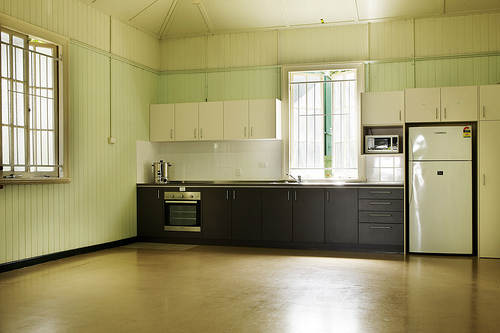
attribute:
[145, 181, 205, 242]
oven — silver oven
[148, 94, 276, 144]
cabinets — dark 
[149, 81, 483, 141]
cabinets — white 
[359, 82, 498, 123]
cabinets — white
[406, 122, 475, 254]
fridge — white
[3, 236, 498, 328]
floor — brown, glared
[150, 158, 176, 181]
coffee maker — silver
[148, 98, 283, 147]
cupboards — white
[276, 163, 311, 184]
faucet — silver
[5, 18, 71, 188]
window — open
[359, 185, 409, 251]
drawers — closed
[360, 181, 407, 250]
drawers — closed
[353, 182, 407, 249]
drawers — closed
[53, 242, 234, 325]
floor — shiny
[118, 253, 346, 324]
floor — shiny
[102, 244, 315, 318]
floor — shiny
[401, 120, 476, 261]
refrigerator — white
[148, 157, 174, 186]
coffee pot — silver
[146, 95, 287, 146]
cabinets — white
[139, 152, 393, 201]
countertop — long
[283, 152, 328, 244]
handles — silver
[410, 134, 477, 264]
refrigerator — white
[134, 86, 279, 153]
cabinets — white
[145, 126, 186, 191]
appliance — silver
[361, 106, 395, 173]
appliance — rectangular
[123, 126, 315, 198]
backsplash — white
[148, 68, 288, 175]
cabinets — white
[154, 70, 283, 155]
cabinets — white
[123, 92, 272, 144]
cabinets — white